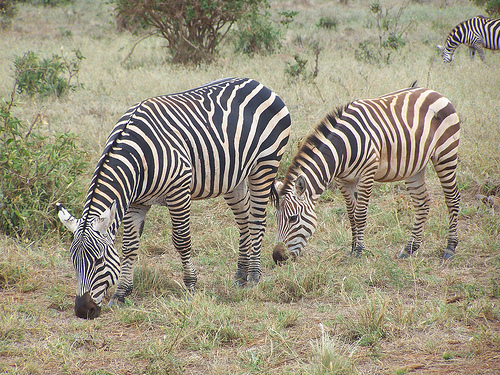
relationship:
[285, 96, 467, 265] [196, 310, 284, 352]
zebra eating grass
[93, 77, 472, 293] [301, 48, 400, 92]
zebras on top of field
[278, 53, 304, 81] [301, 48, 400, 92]
bush on top of field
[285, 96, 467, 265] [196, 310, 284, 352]
zebra obscured by grass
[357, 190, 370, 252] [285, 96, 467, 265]
leg attached to zebra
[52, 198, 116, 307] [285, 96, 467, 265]
face attached to zebra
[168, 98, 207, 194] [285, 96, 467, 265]
stripes on top of zebra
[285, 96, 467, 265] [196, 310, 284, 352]
zebra on top of grass